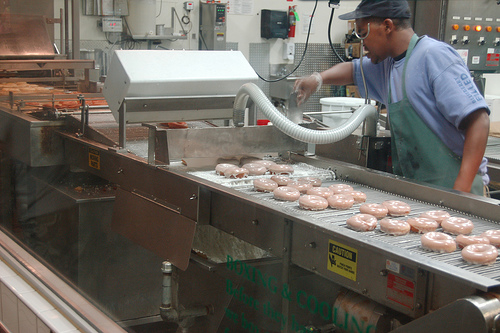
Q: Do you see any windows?
A: Yes, there is a window.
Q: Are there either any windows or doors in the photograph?
A: Yes, there is a window.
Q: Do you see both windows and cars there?
A: No, there is a window but no cars.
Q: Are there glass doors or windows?
A: Yes, there is a glass window.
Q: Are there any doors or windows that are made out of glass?
A: Yes, the window is made of glass.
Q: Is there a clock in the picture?
A: No, there are no clocks.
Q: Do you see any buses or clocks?
A: No, there are no clocks or buses.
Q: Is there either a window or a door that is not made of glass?
A: No, there is a window but it is made of glass.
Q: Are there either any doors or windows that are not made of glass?
A: No, there is a window but it is made of glass.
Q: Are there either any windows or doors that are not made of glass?
A: No, there is a window but it is made of glass.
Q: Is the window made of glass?
A: Yes, the window is made of glass.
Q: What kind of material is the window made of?
A: The window is made of glass.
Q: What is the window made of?
A: The window is made of glass.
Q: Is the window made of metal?
A: No, the window is made of glass.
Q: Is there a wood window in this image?
A: No, there is a window but it is made of glass.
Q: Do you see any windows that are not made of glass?
A: No, there is a window but it is made of glass.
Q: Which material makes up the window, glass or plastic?
A: The window is made of glass.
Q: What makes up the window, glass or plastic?
A: The window is made of glass.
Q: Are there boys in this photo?
A: No, there are no boys.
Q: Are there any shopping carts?
A: No, there are no shopping carts.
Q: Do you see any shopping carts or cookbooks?
A: No, there are no shopping carts or cookbooks.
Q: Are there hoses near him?
A: Yes, there is a hose near the man.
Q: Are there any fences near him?
A: No, there is a hose near the man.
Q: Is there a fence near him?
A: No, there is a hose near the man.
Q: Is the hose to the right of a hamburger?
A: No, the hose is to the right of a donut.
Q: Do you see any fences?
A: No, there are no fences.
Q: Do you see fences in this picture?
A: No, there are no fences.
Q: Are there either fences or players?
A: No, there are no fences or players.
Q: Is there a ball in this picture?
A: No, there are no balls.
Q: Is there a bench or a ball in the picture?
A: No, there are no balls or benches.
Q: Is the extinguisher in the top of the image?
A: Yes, the extinguisher is in the top of the image.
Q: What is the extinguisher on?
A: The extinguisher is on the wall.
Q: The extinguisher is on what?
A: The extinguisher is on the wall.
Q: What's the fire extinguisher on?
A: The extinguisher is on the wall.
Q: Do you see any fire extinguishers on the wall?
A: Yes, there is a fire extinguisher on the wall.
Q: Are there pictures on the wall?
A: No, there is a fire extinguisher on the wall.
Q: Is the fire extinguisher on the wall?
A: Yes, the fire extinguisher is on the wall.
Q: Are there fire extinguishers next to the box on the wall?
A: Yes, there is a fire extinguisher next to the box.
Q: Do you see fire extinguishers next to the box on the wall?
A: Yes, there is a fire extinguisher next to the box.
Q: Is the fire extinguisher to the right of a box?
A: Yes, the fire extinguisher is to the right of a box.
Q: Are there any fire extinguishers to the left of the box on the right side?
A: Yes, there is a fire extinguisher to the left of the box.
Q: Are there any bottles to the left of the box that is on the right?
A: No, there is a fire extinguisher to the left of the box.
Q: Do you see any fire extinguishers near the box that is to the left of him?
A: Yes, there is a fire extinguisher near the box.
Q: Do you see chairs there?
A: No, there are no chairs.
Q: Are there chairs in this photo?
A: No, there are no chairs.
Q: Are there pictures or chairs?
A: No, there are no chairs or pictures.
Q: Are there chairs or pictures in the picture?
A: No, there are no chairs or pictures.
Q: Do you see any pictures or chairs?
A: No, there are no chairs or pictures.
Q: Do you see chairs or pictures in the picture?
A: No, there are no chairs or pictures.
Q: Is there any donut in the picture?
A: Yes, there are donuts.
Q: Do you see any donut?
A: Yes, there are donuts.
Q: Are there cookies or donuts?
A: Yes, there are donuts.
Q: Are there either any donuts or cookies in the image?
A: Yes, there are donuts.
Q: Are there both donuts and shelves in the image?
A: No, there are donuts but no shelves.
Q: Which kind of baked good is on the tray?
A: The food is donuts.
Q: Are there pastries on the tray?
A: No, there are donuts on the tray.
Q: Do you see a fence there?
A: No, there are no fences.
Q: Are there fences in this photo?
A: No, there are no fences.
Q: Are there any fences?
A: No, there are no fences.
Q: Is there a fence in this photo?
A: No, there are no fences.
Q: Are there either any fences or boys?
A: No, there are no fences or boys.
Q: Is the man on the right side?
A: Yes, the man is on the right of the image.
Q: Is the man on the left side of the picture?
A: No, the man is on the right of the image.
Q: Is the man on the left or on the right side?
A: The man is on the right of the image.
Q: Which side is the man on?
A: The man is on the right of the image.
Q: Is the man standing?
A: Yes, the man is standing.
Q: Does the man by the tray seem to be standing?
A: Yes, the man is standing.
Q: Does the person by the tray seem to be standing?
A: Yes, the man is standing.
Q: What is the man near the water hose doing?
A: The man is standing.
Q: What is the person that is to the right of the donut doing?
A: The man is standing.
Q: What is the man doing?
A: The man is standing.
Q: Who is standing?
A: The man is standing.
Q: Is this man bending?
A: No, the man is standing.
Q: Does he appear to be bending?
A: No, the man is standing.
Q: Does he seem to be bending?
A: No, the man is standing.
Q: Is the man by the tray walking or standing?
A: The man is standing.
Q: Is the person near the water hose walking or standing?
A: The man is standing.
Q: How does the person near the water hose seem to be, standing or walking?
A: The man is standing.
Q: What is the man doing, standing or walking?
A: The man is standing.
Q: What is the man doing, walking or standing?
A: The man is standing.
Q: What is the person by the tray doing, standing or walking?
A: The man is standing.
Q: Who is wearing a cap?
A: The man is wearing a cap.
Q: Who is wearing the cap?
A: The man is wearing a cap.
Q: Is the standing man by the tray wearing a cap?
A: Yes, the man is wearing a cap.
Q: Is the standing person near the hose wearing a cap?
A: Yes, the man is wearing a cap.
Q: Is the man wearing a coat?
A: No, the man is wearing a cap.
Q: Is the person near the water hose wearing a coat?
A: No, the man is wearing a cap.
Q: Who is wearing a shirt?
A: The man is wearing a shirt.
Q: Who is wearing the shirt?
A: The man is wearing a shirt.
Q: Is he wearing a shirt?
A: Yes, the man is wearing a shirt.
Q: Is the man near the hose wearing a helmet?
A: No, the man is wearing a shirt.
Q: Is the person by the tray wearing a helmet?
A: No, the man is wearing a shirt.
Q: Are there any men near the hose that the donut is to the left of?
A: Yes, there is a man near the hose.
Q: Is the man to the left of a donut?
A: No, the man is to the right of a donut.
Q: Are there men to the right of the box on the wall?
A: Yes, there is a man to the right of the box.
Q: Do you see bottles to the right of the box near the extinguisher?
A: No, there is a man to the right of the box.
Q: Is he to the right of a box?
A: Yes, the man is to the right of a box.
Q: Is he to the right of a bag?
A: No, the man is to the right of a box.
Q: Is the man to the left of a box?
A: No, the man is to the right of a box.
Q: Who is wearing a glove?
A: The man is wearing a glove.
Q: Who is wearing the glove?
A: The man is wearing a glove.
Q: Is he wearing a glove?
A: Yes, the man is wearing a glove.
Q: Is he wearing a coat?
A: No, the man is wearing a glove.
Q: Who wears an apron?
A: The man wears an apron.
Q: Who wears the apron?
A: The man wears an apron.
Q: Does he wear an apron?
A: Yes, the man wears an apron.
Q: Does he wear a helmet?
A: No, the man wears an apron.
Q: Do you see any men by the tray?
A: Yes, there is a man by the tray.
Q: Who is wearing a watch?
A: The man is wearing a watch.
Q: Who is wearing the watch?
A: The man is wearing a watch.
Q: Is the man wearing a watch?
A: Yes, the man is wearing a watch.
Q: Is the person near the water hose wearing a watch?
A: Yes, the man is wearing a watch.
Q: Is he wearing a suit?
A: No, the man is wearing a watch.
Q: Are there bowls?
A: No, there are no bowls.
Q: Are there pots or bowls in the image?
A: No, there are no bowls or pots.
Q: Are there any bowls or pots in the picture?
A: No, there are no bowls or pots.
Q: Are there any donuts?
A: Yes, there is a donut.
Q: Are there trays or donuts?
A: Yes, there is a donut.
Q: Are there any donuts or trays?
A: Yes, there is a donut.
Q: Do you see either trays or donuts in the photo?
A: Yes, there is a donut.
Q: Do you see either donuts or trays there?
A: Yes, there is a donut.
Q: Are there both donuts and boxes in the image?
A: Yes, there are both a donut and a box.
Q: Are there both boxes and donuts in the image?
A: Yes, there are both a donut and a box.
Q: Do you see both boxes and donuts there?
A: Yes, there are both a donut and a box.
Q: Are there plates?
A: No, there are no plates.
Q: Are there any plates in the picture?
A: No, there are no plates.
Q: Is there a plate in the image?
A: No, there are no plates.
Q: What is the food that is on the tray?
A: The food is a donut.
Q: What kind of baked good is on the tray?
A: The food is a donut.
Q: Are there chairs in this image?
A: No, there are no chairs.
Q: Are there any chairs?
A: No, there are no chairs.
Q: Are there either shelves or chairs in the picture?
A: No, there are no chairs or shelves.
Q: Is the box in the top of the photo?
A: Yes, the box is in the top of the image.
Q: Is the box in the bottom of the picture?
A: No, the box is in the top of the image.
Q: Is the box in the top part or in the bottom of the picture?
A: The box is in the top of the image.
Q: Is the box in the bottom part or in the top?
A: The box is in the top of the image.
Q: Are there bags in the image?
A: No, there are no bags.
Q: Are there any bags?
A: No, there are no bags.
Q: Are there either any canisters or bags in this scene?
A: No, there are no bags or canisters.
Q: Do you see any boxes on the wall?
A: Yes, there is a box on the wall.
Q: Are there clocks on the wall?
A: No, there is a box on the wall.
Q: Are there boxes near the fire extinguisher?
A: Yes, there is a box near the fire extinguisher.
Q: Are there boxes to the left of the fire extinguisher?
A: Yes, there is a box to the left of the fire extinguisher.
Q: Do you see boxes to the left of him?
A: Yes, there is a box to the left of the man.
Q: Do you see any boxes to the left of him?
A: Yes, there is a box to the left of the man.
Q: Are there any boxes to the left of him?
A: Yes, there is a box to the left of the man.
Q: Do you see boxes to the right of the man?
A: No, the box is to the left of the man.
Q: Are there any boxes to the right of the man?
A: No, the box is to the left of the man.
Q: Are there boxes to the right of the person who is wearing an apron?
A: No, the box is to the left of the man.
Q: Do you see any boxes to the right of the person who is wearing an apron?
A: No, the box is to the left of the man.